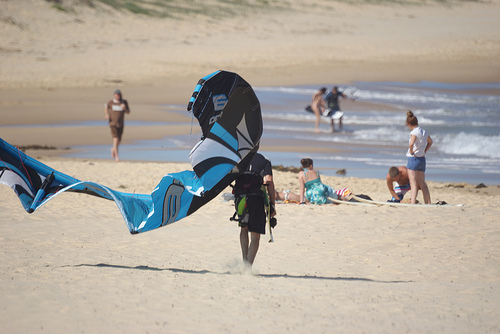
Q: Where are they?
A: Beach.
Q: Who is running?
A: Man.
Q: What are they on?
A: Sand.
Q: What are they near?
A: Water.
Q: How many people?
A: 8.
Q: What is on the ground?
A: Sand.